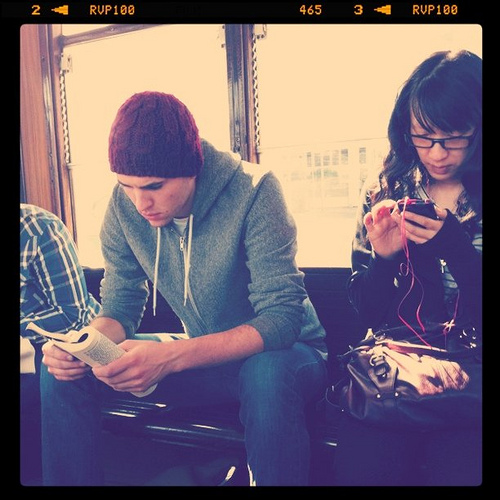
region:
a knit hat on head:
[87, 81, 224, 180]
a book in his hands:
[22, 292, 262, 425]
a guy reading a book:
[34, 82, 346, 489]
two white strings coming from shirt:
[119, 214, 216, 331]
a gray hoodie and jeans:
[36, 121, 340, 391]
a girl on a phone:
[338, 67, 498, 423]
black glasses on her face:
[394, 117, 481, 177]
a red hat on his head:
[101, 92, 214, 184]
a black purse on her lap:
[346, 304, 483, 434]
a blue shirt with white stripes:
[24, 205, 103, 356]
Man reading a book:
[32, 89, 333, 497]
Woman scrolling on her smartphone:
[328, 47, 483, 484]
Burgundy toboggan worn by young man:
[103, 87, 205, 181]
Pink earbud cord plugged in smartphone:
[392, 194, 432, 353]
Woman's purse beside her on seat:
[321, 345, 421, 421]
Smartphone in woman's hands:
[394, 196, 437, 230]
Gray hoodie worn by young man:
[43, 138, 328, 350]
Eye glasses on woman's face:
[401, 132, 473, 152]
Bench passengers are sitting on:
[62, 262, 492, 465]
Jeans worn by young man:
[28, 327, 333, 496]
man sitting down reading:
[41, 90, 305, 474]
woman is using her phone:
[341, 42, 483, 447]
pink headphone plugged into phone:
[390, 187, 445, 343]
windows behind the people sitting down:
[41, 25, 464, 267]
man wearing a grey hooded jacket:
[65, 105, 310, 350]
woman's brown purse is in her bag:
[330, 330, 465, 425]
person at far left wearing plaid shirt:
[16, 200, 91, 375]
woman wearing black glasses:
[397, 125, 474, 150]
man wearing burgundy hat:
[95, 91, 210, 171]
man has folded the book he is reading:
[22, 310, 179, 397]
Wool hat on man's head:
[107, 88, 202, 179]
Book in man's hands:
[26, 322, 156, 393]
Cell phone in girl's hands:
[395, 199, 435, 218]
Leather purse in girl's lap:
[345, 329, 489, 410]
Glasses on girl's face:
[409, 133, 469, 153]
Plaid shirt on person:
[22, 202, 100, 332]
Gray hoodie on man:
[55, 139, 328, 345]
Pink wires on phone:
[401, 199, 428, 346]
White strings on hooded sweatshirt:
[145, 214, 195, 310]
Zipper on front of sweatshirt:
[175, 233, 187, 251]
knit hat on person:
[91, 93, 210, 172]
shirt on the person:
[92, 169, 322, 340]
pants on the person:
[42, 327, 353, 499]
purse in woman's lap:
[335, 323, 487, 426]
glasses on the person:
[403, 125, 470, 152]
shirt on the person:
[358, 164, 480, 336]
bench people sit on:
[37, 255, 476, 460]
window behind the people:
[61, 31, 478, 240]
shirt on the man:
[168, 210, 193, 223]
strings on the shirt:
[131, 234, 221, 311]